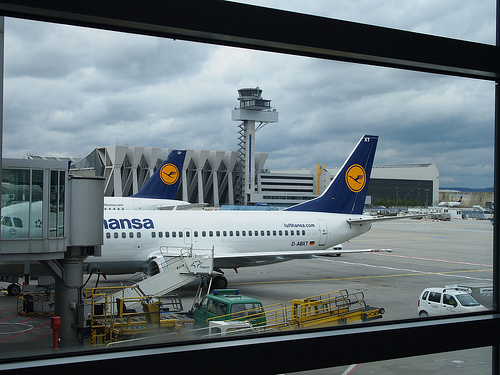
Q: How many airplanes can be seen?
A: Two.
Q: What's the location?
A: Airport.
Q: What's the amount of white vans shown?
A: One.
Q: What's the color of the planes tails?
A: Blue and yellow.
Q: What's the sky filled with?
A: Clouds.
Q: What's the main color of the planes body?
A: White.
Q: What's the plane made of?
A: Metal.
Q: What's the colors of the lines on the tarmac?
A: Yellow and white.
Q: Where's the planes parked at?
A: Tarmac.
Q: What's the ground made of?
A: Cement.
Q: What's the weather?
A: Overcast.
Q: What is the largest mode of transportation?
A: Plane.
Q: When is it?
A: Daytime.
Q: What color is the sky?
A: Gray.